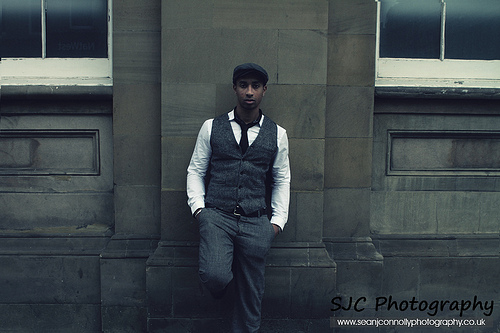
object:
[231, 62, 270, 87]
hat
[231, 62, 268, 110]
head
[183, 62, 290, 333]
man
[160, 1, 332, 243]
brick wall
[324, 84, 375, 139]
section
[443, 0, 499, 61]
pane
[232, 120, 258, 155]
tie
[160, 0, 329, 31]
stonebrick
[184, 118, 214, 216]
sleeve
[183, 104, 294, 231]
shirt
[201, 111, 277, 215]
vest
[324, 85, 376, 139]
brick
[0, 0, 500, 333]
building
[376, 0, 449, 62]
window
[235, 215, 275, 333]
leg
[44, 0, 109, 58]
pane